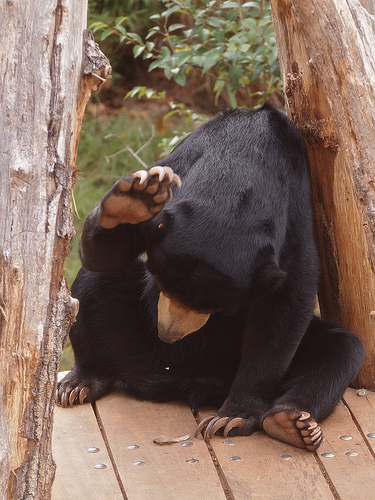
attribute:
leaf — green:
[166, 107, 180, 120]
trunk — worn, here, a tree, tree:
[273, 2, 374, 391]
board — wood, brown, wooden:
[97, 379, 227, 499]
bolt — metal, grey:
[135, 457, 144, 465]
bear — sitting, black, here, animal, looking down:
[56, 107, 363, 452]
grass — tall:
[64, 113, 188, 281]